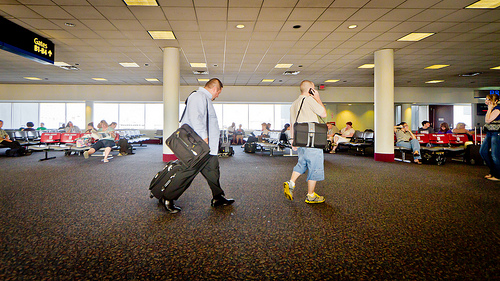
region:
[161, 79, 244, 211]
man is walking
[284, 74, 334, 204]
man is standing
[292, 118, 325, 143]
man is carrying a bag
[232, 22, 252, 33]
light in the ceiling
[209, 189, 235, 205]
man is wearing black shoes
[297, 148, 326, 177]
man is wearing blue shorts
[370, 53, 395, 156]
a white pole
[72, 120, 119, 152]
people sitting down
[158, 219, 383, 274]
the floor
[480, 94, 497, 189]
a women standing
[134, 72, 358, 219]
the men walk through the airport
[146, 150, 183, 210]
the man has a suitcase behind him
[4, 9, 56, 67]
a sign for the travelers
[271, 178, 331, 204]
the man is wearing yellow and grey tennis shoes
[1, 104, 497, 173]
many people are in the airport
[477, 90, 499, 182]
a woman is on the phone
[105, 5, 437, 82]
the ceiling is made up of white tiles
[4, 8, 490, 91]
several lights are on the ceiling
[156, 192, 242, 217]
this mans shoes are black in color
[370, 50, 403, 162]
a pillar can be seen in the distance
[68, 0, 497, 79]
Lights on ceiling.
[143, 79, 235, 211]
Man walking with luggage.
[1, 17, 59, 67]
Gate sign on ceiling.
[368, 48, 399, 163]
Round white support beam.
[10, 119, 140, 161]
People sitting in airport waiting area.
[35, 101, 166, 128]
Sun shining through windows.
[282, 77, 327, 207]
Man talking on cell phone.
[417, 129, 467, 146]
Empty red seats in waiting area.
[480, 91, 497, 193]
Woman talking on cell phone.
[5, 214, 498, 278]
Speckled floor of airport.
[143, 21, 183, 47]
Bright light in the ceiling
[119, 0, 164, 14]
Bright light in the ceiling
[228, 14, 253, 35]
Bright light in the ceiling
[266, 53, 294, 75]
Bright light in the ceiling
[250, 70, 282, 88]
Bright light in the ceiling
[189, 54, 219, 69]
Bright light in the ceiling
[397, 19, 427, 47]
Bright light in the ceiling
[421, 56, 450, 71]
Bright light in the ceiling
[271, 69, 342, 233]
Person walking on the floor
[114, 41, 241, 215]
Person walking on the floor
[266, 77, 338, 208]
person wearing yellow shoes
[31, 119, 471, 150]
red seats in the waiting area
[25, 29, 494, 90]
rectangle shaped lights in the ceiling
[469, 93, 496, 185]
woman on the right side walking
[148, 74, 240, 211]
man with two luggage bags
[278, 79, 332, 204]
man talking on a cellphone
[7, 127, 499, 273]
carpeting in the waiting area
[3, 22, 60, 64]
black eletronic board hanging from the ceiling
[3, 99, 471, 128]
windows along back wall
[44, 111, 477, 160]
people sitting in the waiting area